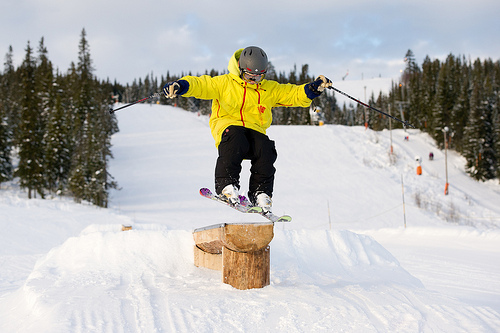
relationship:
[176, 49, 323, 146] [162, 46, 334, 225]
coat on skier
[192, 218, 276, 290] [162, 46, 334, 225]
bench under skier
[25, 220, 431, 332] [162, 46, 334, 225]
hill for skier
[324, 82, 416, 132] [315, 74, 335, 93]
ski pole in hand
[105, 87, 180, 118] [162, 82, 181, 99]
ski pole in hand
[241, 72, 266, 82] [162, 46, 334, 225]
goggles on skier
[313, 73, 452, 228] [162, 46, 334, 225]
ski lift behind skier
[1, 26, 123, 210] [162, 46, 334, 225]
pine tree behind skier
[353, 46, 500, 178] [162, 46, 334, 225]
pine tree behind skier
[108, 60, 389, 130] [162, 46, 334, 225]
pine tree behind skier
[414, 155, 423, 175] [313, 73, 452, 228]
object on ski lift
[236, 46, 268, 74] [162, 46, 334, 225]
helmet on skier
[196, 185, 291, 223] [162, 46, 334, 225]
skis on skier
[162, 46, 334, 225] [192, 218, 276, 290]
skier over bench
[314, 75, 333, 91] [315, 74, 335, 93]
glove on hand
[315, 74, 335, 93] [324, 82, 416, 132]
hand holding ski pole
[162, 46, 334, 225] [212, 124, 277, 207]
skier wearing pants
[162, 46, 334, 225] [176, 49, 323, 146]
skier wearing coat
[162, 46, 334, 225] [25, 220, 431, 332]
skier on hill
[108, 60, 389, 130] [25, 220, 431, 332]
pine tree on hill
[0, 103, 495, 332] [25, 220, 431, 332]
snow on hill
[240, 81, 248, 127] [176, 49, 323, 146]
line on coat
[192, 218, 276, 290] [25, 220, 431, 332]
bench on hill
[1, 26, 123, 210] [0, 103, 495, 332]
pine tree in snow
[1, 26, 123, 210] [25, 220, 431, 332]
pine tree on hill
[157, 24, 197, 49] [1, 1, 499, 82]
clouds in sky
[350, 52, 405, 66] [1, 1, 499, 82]
clouds in sky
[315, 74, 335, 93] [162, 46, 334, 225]
hand on skier